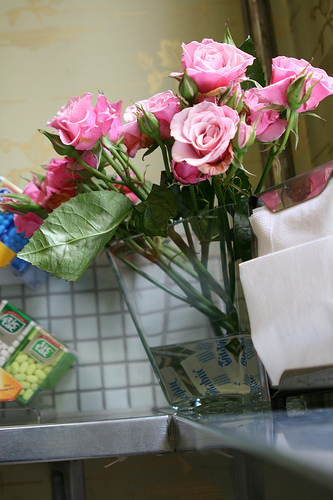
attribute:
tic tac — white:
[44, 365, 53, 374]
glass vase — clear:
[107, 201, 268, 410]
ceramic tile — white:
[14, 281, 173, 414]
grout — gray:
[93, 290, 109, 403]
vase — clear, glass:
[104, 200, 273, 415]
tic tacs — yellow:
[1, 324, 78, 408]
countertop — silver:
[56, 252, 263, 406]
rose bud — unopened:
[130, 98, 159, 137]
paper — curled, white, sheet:
[235, 254, 314, 291]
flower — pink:
[52, 101, 120, 144]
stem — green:
[92, 155, 175, 222]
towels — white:
[220, 195, 327, 374]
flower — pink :
[176, 35, 248, 85]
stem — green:
[257, 151, 276, 183]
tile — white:
[48, 293, 73, 316]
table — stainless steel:
[7, 415, 199, 454]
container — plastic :
[3, 325, 70, 407]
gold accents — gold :
[135, 36, 183, 92]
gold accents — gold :
[0, 2, 150, 49]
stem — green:
[96, 123, 278, 317]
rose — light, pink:
[170, 38, 252, 99]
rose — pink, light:
[169, 100, 238, 179]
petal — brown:
[201, 146, 232, 175]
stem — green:
[207, 172, 236, 302]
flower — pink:
[46, 89, 116, 151]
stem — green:
[84, 130, 242, 339]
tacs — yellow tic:
[2, 329, 63, 399]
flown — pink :
[5, 10, 322, 291]